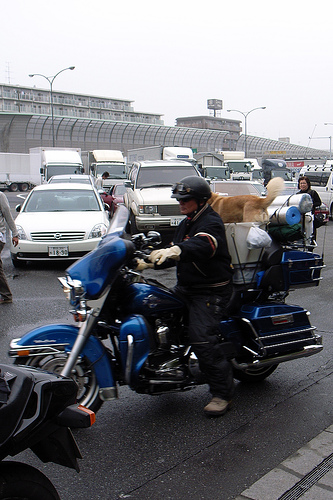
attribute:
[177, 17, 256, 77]
sky — gray, clear, overcast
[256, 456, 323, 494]
single brick — for making ground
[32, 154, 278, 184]
tractor trailors — parked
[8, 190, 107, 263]
car — parked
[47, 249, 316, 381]
motorcycle — blue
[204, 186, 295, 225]
dog — in basket, brown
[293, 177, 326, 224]
woman — walking, walking in back, watching man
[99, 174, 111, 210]
person — standing by car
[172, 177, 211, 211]
helmet — black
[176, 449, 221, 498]
parking lot — busy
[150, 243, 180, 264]
gloves — light colored, tan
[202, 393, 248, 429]
shoes — tan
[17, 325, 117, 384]
fender — blue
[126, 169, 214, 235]
van — white